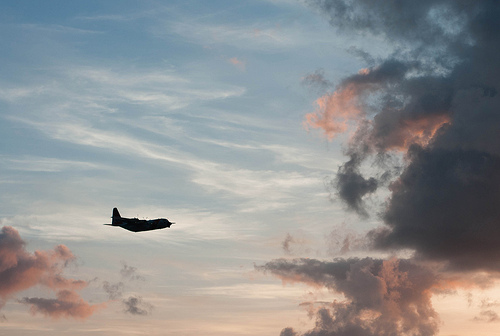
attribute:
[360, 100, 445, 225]
clouds — dark 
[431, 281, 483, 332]
hue — pink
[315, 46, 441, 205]
cloud — tadpole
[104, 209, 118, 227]
tail — airplane's, rear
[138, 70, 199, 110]
clouds — orange, hue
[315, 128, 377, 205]
head — snake's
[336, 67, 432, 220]
sunset — orange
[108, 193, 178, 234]
jet — fighter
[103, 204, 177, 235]
plane — dark color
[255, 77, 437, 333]
clouds — fluffy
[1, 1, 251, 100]
sky — blue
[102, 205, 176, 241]
plane — dark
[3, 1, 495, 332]
sky — evening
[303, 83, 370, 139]
hue — pink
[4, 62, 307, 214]
cloud — white, stratus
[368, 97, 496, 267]
cloud — dark, thunder storm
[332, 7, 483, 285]
storm cloud — dark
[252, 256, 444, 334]
storm cloud — dark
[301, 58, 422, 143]
storm cloud — dark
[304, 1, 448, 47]
storm cloud — dark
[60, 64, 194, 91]
cloud — white, wispy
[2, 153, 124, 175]
cloud — white, wispy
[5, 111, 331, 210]
cloud — white, wispy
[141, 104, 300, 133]
cloud — white, wispy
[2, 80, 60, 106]
cloud — white, wispy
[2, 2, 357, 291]
sky — clear, blue